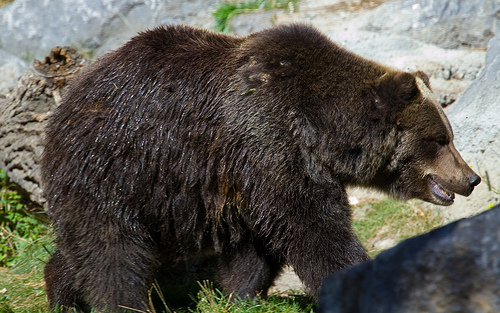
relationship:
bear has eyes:
[36, 20, 493, 312] [431, 132, 458, 151]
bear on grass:
[36, 20, 493, 312] [4, 227, 320, 311]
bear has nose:
[36, 20, 493, 312] [463, 165, 481, 188]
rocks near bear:
[6, 4, 497, 126] [36, 20, 493, 312]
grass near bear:
[4, 227, 320, 311] [36, 20, 493, 312]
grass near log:
[4, 227, 320, 311] [3, 39, 87, 215]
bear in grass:
[36, 20, 493, 312] [4, 227, 320, 311]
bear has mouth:
[36, 20, 493, 312] [417, 168, 462, 204]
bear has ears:
[36, 20, 493, 312] [375, 70, 437, 100]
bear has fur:
[36, 20, 493, 312] [99, 63, 314, 235]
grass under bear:
[4, 227, 320, 311] [36, 20, 493, 312]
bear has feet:
[36, 20, 493, 312] [37, 267, 161, 312]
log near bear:
[3, 39, 87, 215] [36, 20, 493, 312]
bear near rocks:
[36, 20, 493, 312] [6, 4, 497, 126]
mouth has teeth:
[417, 168, 462, 204] [434, 179, 454, 198]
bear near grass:
[36, 20, 493, 312] [4, 227, 320, 311]